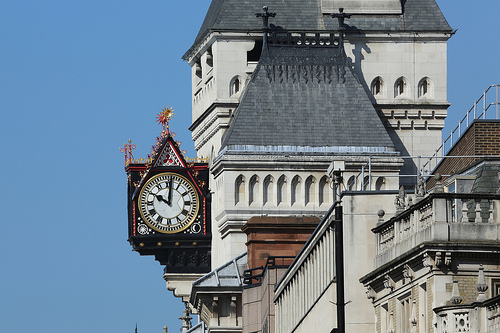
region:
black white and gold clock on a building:
[135, 169, 202, 234]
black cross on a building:
[249, 3, 286, 58]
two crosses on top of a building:
[251, 3, 354, 75]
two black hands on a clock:
[140, 175, 180, 212]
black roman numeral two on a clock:
[177, 187, 192, 197]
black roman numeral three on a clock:
[180, 198, 195, 205]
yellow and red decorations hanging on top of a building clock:
[155, 106, 177, 136]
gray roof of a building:
[213, 47, 405, 157]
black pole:
[325, 198, 351, 331]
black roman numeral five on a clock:
[170, 213, 185, 223]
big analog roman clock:
[130, 157, 215, 241]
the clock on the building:
[137, 172, 196, 231]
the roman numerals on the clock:
[144, 180, 192, 226]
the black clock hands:
[150, 175, 176, 206]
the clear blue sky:
[11, 11, 113, 151]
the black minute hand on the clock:
[165, 175, 170, 200]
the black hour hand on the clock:
[150, 185, 170, 205]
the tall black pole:
[327, 201, 347, 331]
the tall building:
[182, 1, 454, 330]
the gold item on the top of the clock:
[155, 104, 175, 130]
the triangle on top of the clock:
[149, 135, 186, 166]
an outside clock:
[54, 96, 304, 313]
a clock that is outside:
[82, 88, 264, 285]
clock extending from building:
[75, 84, 277, 293]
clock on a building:
[73, 91, 297, 295]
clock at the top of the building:
[58, 67, 354, 332]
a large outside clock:
[58, 84, 271, 314]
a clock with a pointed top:
[90, 55, 313, 330]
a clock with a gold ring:
[87, 84, 252, 262]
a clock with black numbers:
[135, 134, 313, 313]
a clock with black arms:
[89, 97, 269, 330]